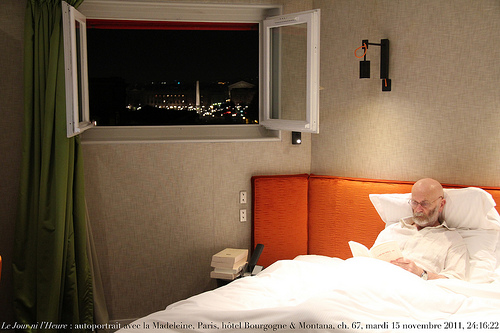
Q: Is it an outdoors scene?
A: Yes, it is outdoors.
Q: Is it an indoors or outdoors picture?
A: It is outdoors.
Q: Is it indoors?
A: No, it is outdoors.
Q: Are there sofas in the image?
A: No, there are no sofas.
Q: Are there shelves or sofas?
A: No, there are no sofas or shelves.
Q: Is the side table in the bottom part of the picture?
A: Yes, the side table is in the bottom of the image.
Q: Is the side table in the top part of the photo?
A: No, the side table is in the bottom of the image.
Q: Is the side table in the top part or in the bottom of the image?
A: The side table is in the bottom of the image.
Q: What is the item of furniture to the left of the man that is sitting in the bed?
A: The piece of furniture is a side table.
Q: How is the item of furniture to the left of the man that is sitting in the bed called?
A: The piece of furniture is a side table.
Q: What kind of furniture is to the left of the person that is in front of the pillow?
A: The piece of furniture is a side table.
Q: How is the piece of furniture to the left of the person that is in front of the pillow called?
A: The piece of furniture is a side table.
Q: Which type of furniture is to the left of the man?
A: The piece of furniture is a side table.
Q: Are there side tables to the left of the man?
A: Yes, there is a side table to the left of the man.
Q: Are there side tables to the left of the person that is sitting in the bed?
A: Yes, there is a side table to the left of the man.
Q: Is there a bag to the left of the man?
A: No, there is a side table to the left of the man.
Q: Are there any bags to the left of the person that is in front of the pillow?
A: No, there is a side table to the left of the man.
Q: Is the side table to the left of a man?
A: Yes, the side table is to the left of a man.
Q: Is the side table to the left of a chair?
A: No, the side table is to the left of a man.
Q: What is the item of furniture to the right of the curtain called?
A: The piece of furniture is a side table.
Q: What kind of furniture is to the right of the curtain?
A: The piece of furniture is a side table.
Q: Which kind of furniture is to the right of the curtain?
A: The piece of furniture is a side table.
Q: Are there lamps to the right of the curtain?
A: No, there is a side table to the right of the curtain.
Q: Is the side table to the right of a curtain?
A: Yes, the side table is to the right of a curtain.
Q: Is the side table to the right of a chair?
A: No, the side table is to the right of a curtain.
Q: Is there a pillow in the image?
A: Yes, there is a pillow.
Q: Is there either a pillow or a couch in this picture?
A: Yes, there is a pillow.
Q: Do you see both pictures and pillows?
A: No, there is a pillow but no pictures.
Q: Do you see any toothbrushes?
A: No, there are no toothbrushes.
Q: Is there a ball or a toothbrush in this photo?
A: No, there are no toothbrushes or balls.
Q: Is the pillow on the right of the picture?
A: Yes, the pillow is on the right of the image.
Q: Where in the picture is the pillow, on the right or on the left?
A: The pillow is on the right of the image.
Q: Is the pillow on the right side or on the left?
A: The pillow is on the right of the image.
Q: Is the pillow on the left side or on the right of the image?
A: The pillow is on the right of the image.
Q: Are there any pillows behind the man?
A: Yes, there is a pillow behind the man.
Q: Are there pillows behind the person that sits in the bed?
A: Yes, there is a pillow behind the man.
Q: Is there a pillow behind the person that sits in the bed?
A: Yes, there is a pillow behind the man.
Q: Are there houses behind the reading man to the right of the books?
A: No, there is a pillow behind the man.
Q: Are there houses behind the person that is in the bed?
A: No, there is a pillow behind the man.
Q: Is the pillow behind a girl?
A: No, the pillow is behind the man.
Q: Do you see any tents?
A: No, there are no tents.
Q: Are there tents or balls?
A: No, there are no tents or balls.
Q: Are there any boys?
A: No, there are no boys.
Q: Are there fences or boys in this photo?
A: No, there are no boys or fences.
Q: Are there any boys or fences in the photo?
A: No, there are no boys or fences.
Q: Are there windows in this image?
A: Yes, there is a window.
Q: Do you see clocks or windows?
A: Yes, there is a window.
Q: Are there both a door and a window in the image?
A: No, there is a window but no doors.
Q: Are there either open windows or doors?
A: Yes, there is an open window.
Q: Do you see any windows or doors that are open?
A: Yes, the window is open.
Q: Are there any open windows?
A: Yes, there is an open window.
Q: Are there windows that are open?
A: Yes, there is a window that is open.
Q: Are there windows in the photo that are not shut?
A: Yes, there is a open window.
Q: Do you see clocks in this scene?
A: No, there are no clocks.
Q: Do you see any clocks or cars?
A: No, there are no clocks or cars.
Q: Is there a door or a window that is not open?
A: No, there is a window but it is open.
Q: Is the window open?
A: Yes, the window is open.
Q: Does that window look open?
A: Yes, the window is open.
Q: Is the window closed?
A: No, the window is open.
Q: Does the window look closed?
A: No, the window is open.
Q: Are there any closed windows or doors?
A: No, there is a window but it is open.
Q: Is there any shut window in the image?
A: No, there is a window but it is open.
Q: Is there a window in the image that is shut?
A: No, there is a window but it is open.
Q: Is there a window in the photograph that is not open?
A: No, there is a window but it is open.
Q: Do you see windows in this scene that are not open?
A: No, there is a window but it is open.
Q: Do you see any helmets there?
A: No, there are no helmets.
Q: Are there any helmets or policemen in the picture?
A: No, there are no helmets or policemen.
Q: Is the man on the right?
A: Yes, the man is on the right of the image.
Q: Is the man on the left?
A: No, the man is on the right of the image.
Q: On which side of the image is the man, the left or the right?
A: The man is on the right of the image.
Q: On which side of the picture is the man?
A: The man is on the right of the image.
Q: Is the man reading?
A: Yes, the man is reading.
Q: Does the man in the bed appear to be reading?
A: Yes, the man is reading.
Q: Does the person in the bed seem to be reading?
A: Yes, the man is reading.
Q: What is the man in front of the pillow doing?
A: The man is reading.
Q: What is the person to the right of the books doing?
A: The man is reading.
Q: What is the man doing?
A: The man is reading.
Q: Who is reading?
A: The man is reading.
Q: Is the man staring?
A: No, the man is reading.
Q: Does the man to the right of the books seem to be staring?
A: No, the man is reading.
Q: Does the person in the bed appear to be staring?
A: No, the man is reading.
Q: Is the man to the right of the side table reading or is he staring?
A: The man is reading.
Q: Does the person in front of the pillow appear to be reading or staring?
A: The man is reading.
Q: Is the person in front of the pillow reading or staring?
A: The man is reading.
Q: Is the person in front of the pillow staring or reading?
A: The man is reading.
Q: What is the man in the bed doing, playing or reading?
A: The man is reading.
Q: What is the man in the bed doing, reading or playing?
A: The man is reading.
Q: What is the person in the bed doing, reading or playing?
A: The man is reading.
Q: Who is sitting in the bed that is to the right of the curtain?
A: The man is sitting in the bed.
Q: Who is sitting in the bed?
A: The man is sitting in the bed.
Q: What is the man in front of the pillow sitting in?
A: The man is sitting in the bed.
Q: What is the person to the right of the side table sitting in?
A: The man is sitting in the bed.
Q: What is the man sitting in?
A: The man is sitting in the bed.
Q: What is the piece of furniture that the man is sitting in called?
A: The piece of furniture is a bed.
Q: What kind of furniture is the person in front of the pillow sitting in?
A: The man is sitting in the bed.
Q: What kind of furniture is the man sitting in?
A: The man is sitting in the bed.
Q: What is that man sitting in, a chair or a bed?
A: The man is sitting in a bed.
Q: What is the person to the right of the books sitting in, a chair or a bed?
A: The man is sitting in a bed.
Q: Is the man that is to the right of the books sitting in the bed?
A: Yes, the man is sitting in the bed.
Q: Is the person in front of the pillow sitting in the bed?
A: Yes, the man is sitting in the bed.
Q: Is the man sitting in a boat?
A: No, the man is sitting in the bed.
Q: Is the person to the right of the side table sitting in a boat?
A: No, the man is sitting in the bed.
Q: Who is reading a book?
A: The man is reading a book.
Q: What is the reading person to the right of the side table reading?
A: The man is reading a book.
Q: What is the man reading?
A: The man is reading a book.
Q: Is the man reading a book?
A: Yes, the man is reading a book.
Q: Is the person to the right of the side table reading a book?
A: Yes, the man is reading a book.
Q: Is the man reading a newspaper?
A: No, the man is reading a book.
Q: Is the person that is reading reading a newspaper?
A: No, the man is reading a book.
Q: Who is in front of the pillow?
A: The man is in front of the pillow.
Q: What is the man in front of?
A: The man is in front of the pillow.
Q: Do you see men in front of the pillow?
A: Yes, there is a man in front of the pillow.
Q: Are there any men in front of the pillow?
A: Yes, there is a man in front of the pillow.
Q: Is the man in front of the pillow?
A: Yes, the man is in front of the pillow.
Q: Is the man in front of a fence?
A: No, the man is in front of the pillow.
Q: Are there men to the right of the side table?
A: Yes, there is a man to the right of the side table.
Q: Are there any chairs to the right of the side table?
A: No, there is a man to the right of the side table.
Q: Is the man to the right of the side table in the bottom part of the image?
A: Yes, the man is to the right of the side table.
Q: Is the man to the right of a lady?
A: No, the man is to the right of the side table.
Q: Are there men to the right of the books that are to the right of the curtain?
A: Yes, there is a man to the right of the books.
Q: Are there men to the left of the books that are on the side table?
A: No, the man is to the right of the books.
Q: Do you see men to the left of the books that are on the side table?
A: No, the man is to the right of the books.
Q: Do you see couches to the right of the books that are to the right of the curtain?
A: No, there is a man to the right of the books.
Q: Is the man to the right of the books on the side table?
A: Yes, the man is to the right of the books.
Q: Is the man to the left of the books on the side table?
A: No, the man is to the right of the books.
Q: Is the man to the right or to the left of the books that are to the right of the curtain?
A: The man is to the right of the books.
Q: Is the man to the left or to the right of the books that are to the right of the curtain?
A: The man is to the right of the books.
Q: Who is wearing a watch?
A: The man is wearing a watch.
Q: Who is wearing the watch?
A: The man is wearing a watch.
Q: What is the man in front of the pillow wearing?
A: The man is wearing a watch.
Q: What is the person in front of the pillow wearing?
A: The man is wearing a watch.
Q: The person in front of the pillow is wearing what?
A: The man is wearing a watch.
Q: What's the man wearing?
A: The man is wearing a watch.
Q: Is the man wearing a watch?
A: Yes, the man is wearing a watch.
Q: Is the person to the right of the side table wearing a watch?
A: Yes, the man is wearing a watch.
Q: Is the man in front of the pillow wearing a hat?
A: No, the man is wearing a watch.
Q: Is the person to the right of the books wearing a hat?
A: No, the man is wearing a watch.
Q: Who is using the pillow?
A: The man is using the pillow.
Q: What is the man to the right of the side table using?
A: The man is using a pillow.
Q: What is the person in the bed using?
A: The man is using a pillow.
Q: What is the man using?
A: The man is using a pillow.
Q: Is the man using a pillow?
A: Yes, the man is using a pillow.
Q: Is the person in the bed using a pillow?
A: Yes, the man is using a pillow.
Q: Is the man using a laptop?
A: No, the man is using a pillow.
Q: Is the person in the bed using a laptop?
A: No, the man is using a pillow.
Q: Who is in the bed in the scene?
A: The man is in the bed.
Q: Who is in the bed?
A: The man is in the bed.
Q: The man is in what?
A: The man is in the bed.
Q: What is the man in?
A: The man is in the bed.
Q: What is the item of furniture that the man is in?
A: The piece of furniture is a bed.